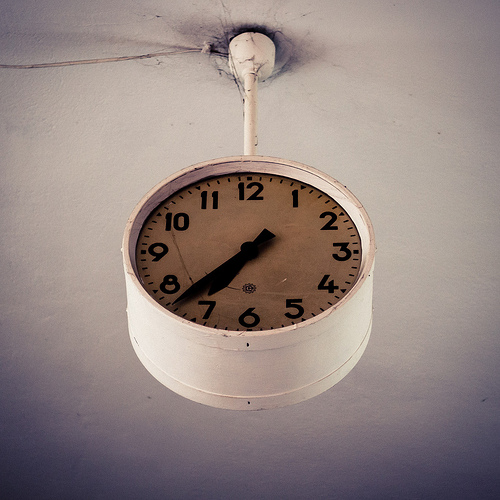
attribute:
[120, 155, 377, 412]
clock — white, large, round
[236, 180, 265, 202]
number — 12, black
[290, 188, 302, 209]
number — one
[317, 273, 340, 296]
number — four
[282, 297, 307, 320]
number — five, black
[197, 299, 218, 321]
number — seven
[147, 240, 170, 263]
number — nine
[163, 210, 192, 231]
number — ten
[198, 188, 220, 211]
number — eleven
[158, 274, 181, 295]
number — eight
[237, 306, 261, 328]
number — six, black, 6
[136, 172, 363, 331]
face — round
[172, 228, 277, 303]
hand — black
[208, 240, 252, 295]
hand — black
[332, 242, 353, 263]
number — black, 3